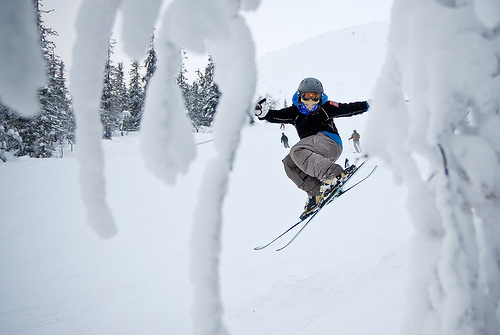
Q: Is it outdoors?
A: Yes, it is outdoors.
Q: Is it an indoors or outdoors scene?
A: It is outdoors.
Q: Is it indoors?
A: No, it is outdoors.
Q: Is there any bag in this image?
A: No, there are no bags.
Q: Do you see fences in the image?
A: No, there are no fences.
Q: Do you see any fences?
A: No, there are no fences.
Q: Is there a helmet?
A: Yes, there is a helmet.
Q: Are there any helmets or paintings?
A: Yes, there is a helmet.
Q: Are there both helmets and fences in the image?
A: No, there is a helmet but no fences.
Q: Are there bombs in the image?
A: No, there are no bombs.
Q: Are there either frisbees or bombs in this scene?
A: No, there are no bombs or frisbees.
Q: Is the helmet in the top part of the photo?
A: Yes, the helmet is in the top of the image.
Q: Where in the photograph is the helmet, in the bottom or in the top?
A: The helmet is in the top of the image.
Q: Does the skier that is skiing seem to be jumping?
A: Yes, the skier is jumping.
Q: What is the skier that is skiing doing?
A: The skier is jumping.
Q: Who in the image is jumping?
A: The skier is jumping.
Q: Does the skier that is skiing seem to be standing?
A: No, the skier is jumping.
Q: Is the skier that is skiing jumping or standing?
A: The skier is jumping.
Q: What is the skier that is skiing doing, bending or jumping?
A: The skier is jumping.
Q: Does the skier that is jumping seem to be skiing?
A: Yes, the skier is skiing.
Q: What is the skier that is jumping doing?
A: The skier is skiing.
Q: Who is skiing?
A: The skier is skiing.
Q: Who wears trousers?
A: The skier wears trousers.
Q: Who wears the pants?
A: The skier wears trousers.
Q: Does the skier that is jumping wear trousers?
A: Yes, the skier wears trousers.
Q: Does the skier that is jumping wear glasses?
A: No, the skier wears trousers.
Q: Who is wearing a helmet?
A: The skier is wearing a helmet.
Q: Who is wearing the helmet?
A: The skier is wearing a helmet.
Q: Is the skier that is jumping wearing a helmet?
A: Yes, the skier is wearing a helmet.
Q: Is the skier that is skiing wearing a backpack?
A: No, the skier is wearing a helmet.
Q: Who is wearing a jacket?
A: The skier is wearing a jacket.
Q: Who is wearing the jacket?
A: The skier is wearing a jacket.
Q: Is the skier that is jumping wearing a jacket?
A: Yes, the skier is wearing a jacket.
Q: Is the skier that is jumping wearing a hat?
A: No, the skier is wearing a jacket.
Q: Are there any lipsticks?
A: No, there are no lipsticks.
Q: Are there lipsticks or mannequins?
A: No, there are no lipsticks or mannequins.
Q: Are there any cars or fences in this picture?
A: No, there are no cars or fences.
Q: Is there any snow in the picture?
A: Yes, there is snow.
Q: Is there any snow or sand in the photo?
A: Yes, there is snow.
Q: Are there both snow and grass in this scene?
A: No, there is snow but no grass.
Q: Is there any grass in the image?
A: No, there is no grass.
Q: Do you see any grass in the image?
A: No, there is no grass.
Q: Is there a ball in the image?
A: No, there are no balls.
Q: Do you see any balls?
A: No, there are no balls.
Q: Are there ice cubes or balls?
A: No, there are no balls or ice cubes.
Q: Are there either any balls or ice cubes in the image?
A: No, there are no balls or ice cubes.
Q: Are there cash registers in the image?
A: No, there are no cash registers.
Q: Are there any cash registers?
A: No, there are no cash registers.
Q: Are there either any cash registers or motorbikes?
A: No, there are no cash registers or motorbikes.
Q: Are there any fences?
A: No, there are no fences.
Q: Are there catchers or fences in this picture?
A: No, there are no fences or catchers.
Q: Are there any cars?
A: No, there are no cars.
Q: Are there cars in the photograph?
A: No, there are no cars.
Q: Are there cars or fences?
A: No, there are no cars or fences.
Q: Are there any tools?
A: No, there are no tools.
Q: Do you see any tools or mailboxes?
A: No, there are no tools or mailboxes.